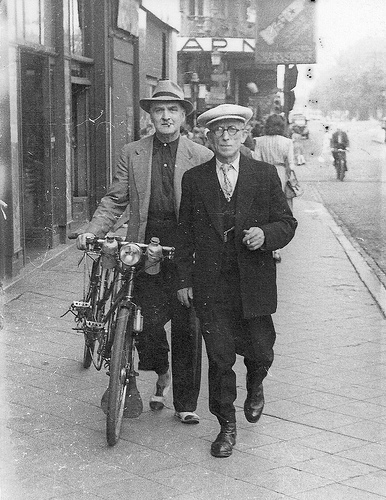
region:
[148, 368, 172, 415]
man wear white and black shoes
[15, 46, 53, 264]
door open with wooden trim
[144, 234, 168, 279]
metal bottle on handle bars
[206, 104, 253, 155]
man with round black glasses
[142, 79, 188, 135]
man with tan dress hat on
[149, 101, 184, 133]
man with cigar in mouth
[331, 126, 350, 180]
man riding bicycle in distance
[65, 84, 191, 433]
man holding up bicycle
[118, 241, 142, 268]
chrome headlight on bicycle by man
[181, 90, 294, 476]
this is a person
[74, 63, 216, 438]
this is a person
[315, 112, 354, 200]
this is a person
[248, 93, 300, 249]
this is a person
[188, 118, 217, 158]
this is a person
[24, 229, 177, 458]
this is a bike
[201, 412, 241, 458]
this is a shoe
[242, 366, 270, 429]
this is a shoe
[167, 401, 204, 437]
this is a shoe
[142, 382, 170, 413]
this is a shoe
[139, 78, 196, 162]
man is smoking a cigar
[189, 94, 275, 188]
man wearing a hat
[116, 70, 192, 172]
man wearing a hat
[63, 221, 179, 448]
bicycle on pavement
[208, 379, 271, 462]
pair of black boots on pavement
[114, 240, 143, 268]
headlight on front of bicycle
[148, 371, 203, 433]
pair of black and white shoes walking on pavement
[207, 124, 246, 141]
pair of glasses on man walking on sidewalk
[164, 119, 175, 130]
cigarette in man's mouth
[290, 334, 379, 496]
square tiles on pavement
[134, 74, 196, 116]
fedora hat with black stripe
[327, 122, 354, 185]
man riding bicycle down the street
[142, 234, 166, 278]
metal bottle attached to bicycle handle bars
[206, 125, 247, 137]
round glasses that are mens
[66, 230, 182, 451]
bicycle being pushed by man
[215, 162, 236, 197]
man wearing a tie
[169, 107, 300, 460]
elderly man walking on sidewalk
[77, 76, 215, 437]
man pushing bike smoking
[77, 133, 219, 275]
suit jacket of man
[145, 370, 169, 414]
two toned mens shoes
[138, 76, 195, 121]
hat with band being worn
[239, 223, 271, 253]
man holding cigarette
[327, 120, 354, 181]
person riding bicycle in distance